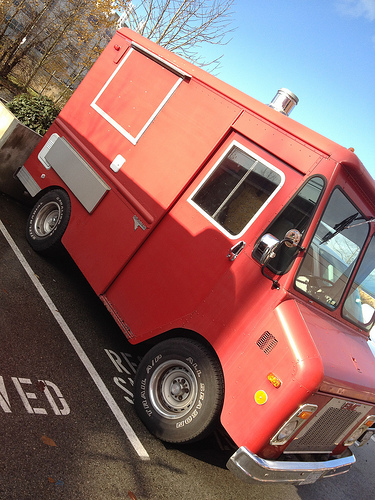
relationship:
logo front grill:
[341, 401, 361, 411] [286, 389, 371, 464]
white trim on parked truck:
[91, 45, 184, 145] [16, 27, 374, 487]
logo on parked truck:
[314, 376, 375, 426] [16, 27, 374, 487]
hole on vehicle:
[251, 327, 279, 357] [34, 8, 367, 319]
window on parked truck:
[186, 138, 286, 240] [16, 27, 374, 487]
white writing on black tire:
[54, 195, 63, 224] [22, 185, 69, 253]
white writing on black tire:
[27, 200, 43, 238] [22, 185, 69, 253]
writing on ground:
[0, 372, 72, 417] [3, 242, 162, 496]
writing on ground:
[113, 342, 130, 395] [3, 242, 162, 496]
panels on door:
[185, 131, 288, 248] [100, 129, 303, 333]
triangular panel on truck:
[251, 174, 327, 272] [14, 26, 373, 486]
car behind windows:
[257, 224, 373, 325] [246, 167, 372, 332]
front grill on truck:
[297, 406, 362, 446] [14, 26, 373, 486]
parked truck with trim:
[16, 27, 374, 487] [87, 94, 131, 143]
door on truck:
[100, 129, 303, 333] [14, 26, 373, 486]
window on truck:
[186, 139, 285, 240] [14, 26, 373, 486]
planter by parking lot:
[1, 95, 39, 191] [2, 74, 372, 498]